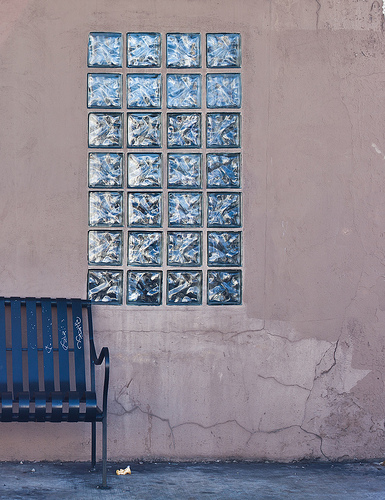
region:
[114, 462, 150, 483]
An apple core laying on the ground.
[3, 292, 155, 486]
The bench is blue.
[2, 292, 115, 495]
The bench is metal.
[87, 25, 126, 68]
The window is square.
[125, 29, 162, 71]
The window is square.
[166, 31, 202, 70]
The window is square.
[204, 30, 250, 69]
The window is square.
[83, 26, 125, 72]
The window is blue.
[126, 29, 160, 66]
The window is blue.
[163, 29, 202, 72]
The window is blue.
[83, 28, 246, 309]
small square glass windows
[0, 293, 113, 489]
a black metal bench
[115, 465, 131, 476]
a small piece of litter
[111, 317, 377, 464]
cracks in the stone wall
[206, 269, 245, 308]
a square glass window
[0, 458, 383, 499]
a black cement ground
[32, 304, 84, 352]
markings on the bench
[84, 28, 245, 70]
the top row of the window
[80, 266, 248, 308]
the bottom row of a window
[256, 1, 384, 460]
a tan cement wall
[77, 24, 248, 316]
square decorations on wall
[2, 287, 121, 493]
end of metal bench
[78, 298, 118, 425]
arm rest railing of metal bench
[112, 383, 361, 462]
crack in light pink colored wall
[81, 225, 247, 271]
row of four square decorations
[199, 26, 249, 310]
column of seven square decorations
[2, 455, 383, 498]
side walk next to building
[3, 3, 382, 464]
light pink side of building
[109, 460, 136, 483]
piece of trash on side walk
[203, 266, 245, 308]
bottom right square decoration in building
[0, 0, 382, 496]
A bench is next to the wall.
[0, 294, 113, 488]
The bench is made out of black metal.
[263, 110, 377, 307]
The wall is beige.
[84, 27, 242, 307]
The window has a frosted look to it.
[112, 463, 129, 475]
Trash is on the ground.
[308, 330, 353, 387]
Cracks on the wall.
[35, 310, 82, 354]
Graffiti on the bench.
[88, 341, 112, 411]
An arm rest on the bench.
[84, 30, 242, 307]
The window is made up of multiple square pieces of glass.